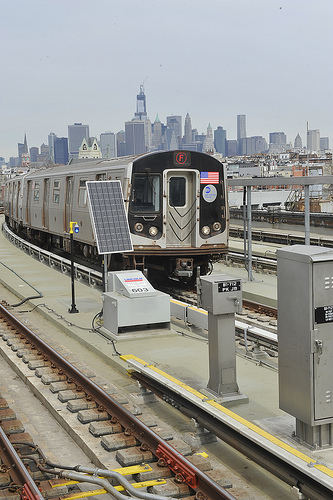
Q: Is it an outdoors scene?
A: Yes, it is outdoors.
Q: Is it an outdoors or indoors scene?
A: It is outdoors.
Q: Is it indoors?
A: No, it is outdoors.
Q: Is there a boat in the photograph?
A: No, there are no boats.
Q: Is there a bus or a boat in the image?
A: No, there are no boats or buses.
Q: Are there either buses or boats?
A: No, there are no boats or buses.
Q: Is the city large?
A: Yes, the city is large.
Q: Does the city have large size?
A: Yes, the city is large.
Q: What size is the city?
A: The city is large.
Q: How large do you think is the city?
A: The city is large.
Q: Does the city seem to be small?
A: No, the city is large.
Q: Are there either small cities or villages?
A: No, there is a city but it is large.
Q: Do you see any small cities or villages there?
A: No, there is a city but it is large.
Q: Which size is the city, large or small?
A: The city is large.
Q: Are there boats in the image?
A: No, there are no boats.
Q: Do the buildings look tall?
A: Yes, the buildings are tall.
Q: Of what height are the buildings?
A: The buildings are tall.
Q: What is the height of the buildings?
A: The buildings are tall.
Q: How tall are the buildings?
A: The buildings are tall.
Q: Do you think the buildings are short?
A: No, the buildings are tall.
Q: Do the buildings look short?
A: No, the buildings are tall.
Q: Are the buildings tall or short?
A: The buildings are tall.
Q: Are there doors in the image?
A: Yes, there are doors.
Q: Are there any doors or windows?
A: Yes, there are doors.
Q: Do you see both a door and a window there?
A: Yes, there are both a door and a window.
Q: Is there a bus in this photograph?
A: No, there are no buses.